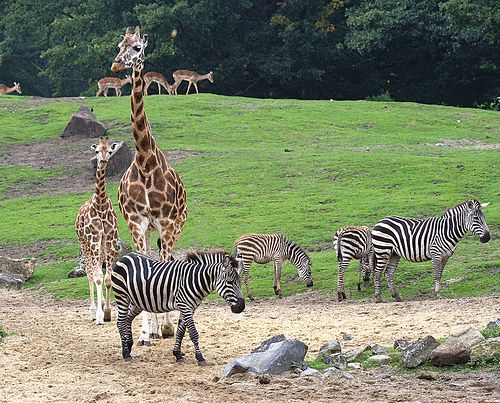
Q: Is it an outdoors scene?
A: Yes, it is outdoors.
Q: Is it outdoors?
A: Yes, it is outdoors.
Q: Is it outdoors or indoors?
A: It is outdoors.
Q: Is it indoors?
A: No, it is outdoors.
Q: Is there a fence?
A: No, there are no fences.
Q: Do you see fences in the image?
A: No, there are no fences.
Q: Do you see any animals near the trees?
A: Yes, there are animals near the trees.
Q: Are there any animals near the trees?
A: Yes, there are animals near the trees.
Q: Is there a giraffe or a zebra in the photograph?
A: Yes, there are zebras.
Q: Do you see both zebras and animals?
A: Yes, there are both zebras and animals.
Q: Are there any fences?
A: No, there are no fences.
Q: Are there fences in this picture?
A: No, there are no fences.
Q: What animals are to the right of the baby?
A: The animals are zebras.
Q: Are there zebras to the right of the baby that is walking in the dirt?
A: Yes, there are zebras to the right of the baby.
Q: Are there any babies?
A: Yes, there is a baby.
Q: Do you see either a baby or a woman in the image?
A: Yes, there is a baby.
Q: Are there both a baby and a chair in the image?
A: No, there is a baby but no chairs.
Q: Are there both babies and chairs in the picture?
A: No, there is a baby but no chairs.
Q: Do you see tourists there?
A: No, there are no tourists.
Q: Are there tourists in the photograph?
A: No, there are no tourists.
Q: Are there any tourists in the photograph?
A: No, there are no tourists.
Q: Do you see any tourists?
A: No, there are no tourists.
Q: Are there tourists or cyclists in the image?
A: No, there are no tourists or cyclists.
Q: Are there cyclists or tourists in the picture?
A: No, there are no tourists or cyclists.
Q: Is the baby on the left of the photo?
A: Yes, the baby is on the left of the image.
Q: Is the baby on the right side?
A: No, the baby is on the left of the image.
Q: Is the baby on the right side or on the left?
A: The baby is on the left of the image.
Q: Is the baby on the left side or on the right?
A: The baby is on the left of the image.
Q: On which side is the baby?
A: The baby is on the left of the image.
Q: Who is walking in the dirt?
A: The baby is walking in the dirt.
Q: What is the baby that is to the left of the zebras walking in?
A: The baby is walking in the dirt.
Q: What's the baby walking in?
A: The baby is walking in the dirt.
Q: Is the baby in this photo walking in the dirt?
A: Yes, the baby is walking in the dirt.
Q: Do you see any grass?
A: Yes, there is grass.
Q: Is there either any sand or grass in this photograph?
A: Yes, there is grass.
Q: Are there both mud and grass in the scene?
A: No, there is grass but no mud.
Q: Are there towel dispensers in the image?
A: No, there are no towel dispensers.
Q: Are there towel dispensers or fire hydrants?
A: No, there are no towel dispensers or fire hydrants.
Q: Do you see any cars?
A: No, there are no cars.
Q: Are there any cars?
A: No, there are no cars.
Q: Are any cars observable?
A: No, there are no cars.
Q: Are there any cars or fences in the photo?
A: No, there are no cars or fences.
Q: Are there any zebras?
A: Yes, there is a zebra.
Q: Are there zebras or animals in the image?
A: Yes, there is a zebra.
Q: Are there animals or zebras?
A: Yes, there is a zebra.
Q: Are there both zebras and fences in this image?
A: No, there is a zebra but no fences.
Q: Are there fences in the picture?
A: No, there are no fences.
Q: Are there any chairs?
A: No, there are no chairs.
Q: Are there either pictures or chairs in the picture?
A: No, there are no chairs or pictures.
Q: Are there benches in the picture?
A: No, there are no benches.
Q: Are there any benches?
A: No, there are no benches.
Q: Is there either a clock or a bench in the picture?
A: No, there are no benches or clocks.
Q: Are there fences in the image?
A: No, there are no fences.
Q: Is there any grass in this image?
A: Yes, there is grass.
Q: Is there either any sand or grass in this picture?
A: Yes, there is grass.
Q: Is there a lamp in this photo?
A: No, there are no lamps.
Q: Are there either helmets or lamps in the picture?
A: No, there are no lamps or helmets.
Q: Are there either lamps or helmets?
A: No, there are no lamps or helmets.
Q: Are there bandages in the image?
A: No, there are no bandages.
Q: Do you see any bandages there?
A: No, there are no bandages.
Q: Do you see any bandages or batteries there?
A: No, there are no bandages or batteries.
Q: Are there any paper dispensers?
A: No, there are no paper dispensers.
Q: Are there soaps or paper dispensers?
A: No, there are no paper dispensers or soaps.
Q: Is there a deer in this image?
A: Yes, there is a deer.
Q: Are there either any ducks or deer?
A: Yes, there is a deer.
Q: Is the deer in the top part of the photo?
A: Yes, the deer is in the top of the image.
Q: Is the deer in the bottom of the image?
A: No, the deer is in the top of the image.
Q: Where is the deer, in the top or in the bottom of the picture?
A: The deer is in the top of the image.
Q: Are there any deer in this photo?
A: Yes, there is a deer.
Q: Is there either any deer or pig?
A: Yes, there is a deer.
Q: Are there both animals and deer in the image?
A: Yes, there are both a deer and animals.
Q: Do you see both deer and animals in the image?
A: Yes, there are both a deer and animals.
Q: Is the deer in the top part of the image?
A: Yes, the deer is in the top of the image.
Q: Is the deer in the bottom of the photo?
A: No, the deer is in the top of the image.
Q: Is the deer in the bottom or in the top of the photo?
A: The deer is in the top of the image.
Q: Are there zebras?
A: Yes, there is a zebra.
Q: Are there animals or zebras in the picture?
A: Yes, there is a zebra.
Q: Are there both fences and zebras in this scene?
A: No, there is a zebra but no fences.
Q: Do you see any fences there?
A: No, there are no fences.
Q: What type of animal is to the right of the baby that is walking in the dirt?
A: The animal is a zebra.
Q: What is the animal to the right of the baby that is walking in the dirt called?
A: The animal is a zebra.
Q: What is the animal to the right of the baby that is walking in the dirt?
A: The animal is a zebra.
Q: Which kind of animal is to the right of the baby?
A: The animal is a zebra.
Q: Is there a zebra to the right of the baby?
A: Yes, there is a zebra to the right of the baby.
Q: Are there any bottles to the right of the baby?
A: No, there is a zebra to the right of the baby.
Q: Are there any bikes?
A: No, there are no bikes.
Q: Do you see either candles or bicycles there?
A: No, there are no bicycles or candles.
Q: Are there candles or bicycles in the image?
A: No, there are no bicycles or candles.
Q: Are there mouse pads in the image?
A: No, there are no mouse pads.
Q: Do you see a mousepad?
A: No, there are no mouse pads.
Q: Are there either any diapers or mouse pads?
A: No, there are no mouse pads or diapers.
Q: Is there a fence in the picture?
A: No, there are no fences.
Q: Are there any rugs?
A: No, there are no rugs.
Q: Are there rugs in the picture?
A: No, there are no rugs.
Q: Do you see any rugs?
A: No, there are no rugs.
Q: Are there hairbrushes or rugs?
A: No, there are no rugs or hairbrushes.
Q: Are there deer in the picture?
A: Yes, there is a deer.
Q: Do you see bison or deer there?
A: Yes, there is a deer.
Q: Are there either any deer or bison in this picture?
A: Yes, there is a deer.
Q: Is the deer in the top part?
A: Yes, the deer is in the top of the image.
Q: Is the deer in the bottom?
A: No, the deer is in the top of the image.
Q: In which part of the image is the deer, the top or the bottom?
A: The deer is in the top of the image.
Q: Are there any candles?
A: No, there are no candles.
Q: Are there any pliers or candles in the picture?
A: No, there are no candles or pliers.